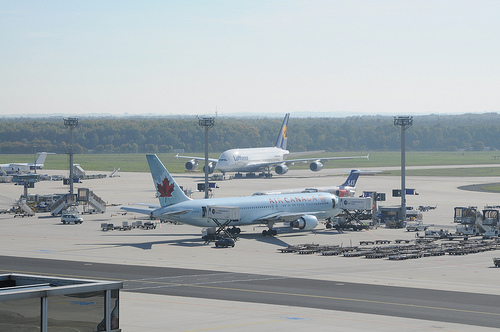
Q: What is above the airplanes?
A: The sky.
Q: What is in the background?
A: Trees.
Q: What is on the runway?
A: Airplanes.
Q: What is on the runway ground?
A: Airline equipment.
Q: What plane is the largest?
A: The white plane.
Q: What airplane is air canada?
A: The blue airplane.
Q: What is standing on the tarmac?
A: Lamp posts.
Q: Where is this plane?
A: On the tarmac.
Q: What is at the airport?
A: Airplanes.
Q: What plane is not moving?
A: An Air Canada plane.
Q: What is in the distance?
A: A distant tree line.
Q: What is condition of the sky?
A: Clear.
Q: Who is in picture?
A: No one.